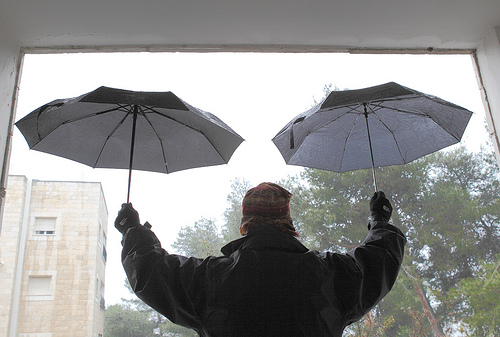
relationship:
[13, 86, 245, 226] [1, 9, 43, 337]
umbrella on left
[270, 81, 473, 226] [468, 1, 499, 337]
umbrella on right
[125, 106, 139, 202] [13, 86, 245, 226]
pole of umbrella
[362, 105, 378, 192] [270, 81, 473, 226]
pole of umbrella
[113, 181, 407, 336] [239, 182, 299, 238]
person wearing hat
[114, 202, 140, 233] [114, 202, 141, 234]
glove on hand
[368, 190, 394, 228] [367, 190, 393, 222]
glove on right hand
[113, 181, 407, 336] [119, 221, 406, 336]
person wearing jacket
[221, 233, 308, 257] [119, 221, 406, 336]
collar of jacket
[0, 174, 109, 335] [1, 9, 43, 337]
building on left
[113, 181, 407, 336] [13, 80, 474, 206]
person holding umbrellas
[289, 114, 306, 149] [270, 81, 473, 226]
strap on umbrella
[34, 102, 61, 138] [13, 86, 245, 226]
strap on umbrella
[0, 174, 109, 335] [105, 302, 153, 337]
building next to tree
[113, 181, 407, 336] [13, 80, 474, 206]
person holds umbrellas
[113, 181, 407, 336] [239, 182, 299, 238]
person wears hat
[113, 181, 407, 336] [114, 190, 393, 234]
person wears gloves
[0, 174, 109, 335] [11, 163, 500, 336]
building in background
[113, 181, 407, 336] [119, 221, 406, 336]
person wears jacket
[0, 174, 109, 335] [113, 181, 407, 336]
building behind person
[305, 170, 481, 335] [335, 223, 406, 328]
tree behind arm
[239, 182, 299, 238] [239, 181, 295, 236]
hat on head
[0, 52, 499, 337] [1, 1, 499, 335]
doorway of building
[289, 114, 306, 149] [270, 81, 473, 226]
strap hanging from umbrella